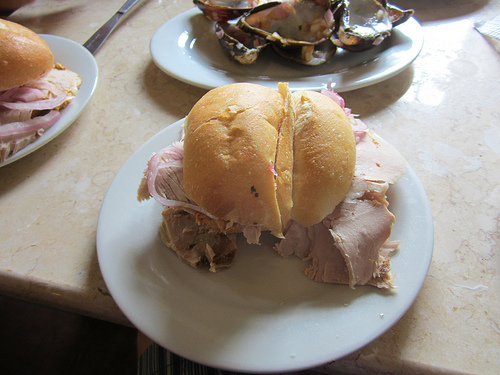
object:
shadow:
[102, 238, 401, 360]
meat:
[134, 81, 401, 296]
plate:
[92, 115, 437, 373]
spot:
[243, 183, 264, 199]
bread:
[184, 80, 359, 240]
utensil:
[81, 0, 143, 54]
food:
[186, 0, 416, 68]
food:
[140, 81, 398, 297]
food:
[1, 17, 80, 160]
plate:
[151, 3, 425, 90]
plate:
[3, 30, 99, 169]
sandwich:
[140, 79, 401, 297]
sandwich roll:
[184, 80, 360, 231]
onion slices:
[4, 90, 69, 142]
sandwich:
[0, 16, 80, 156]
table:
[0, 2, 499, 371]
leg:
[130, 324, 178, 373]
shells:
[192, 12, 385, 68]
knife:
[81, 0, 153, 56]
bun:
[188, 71, 376, 258]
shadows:
[177, 25, 407, 90]